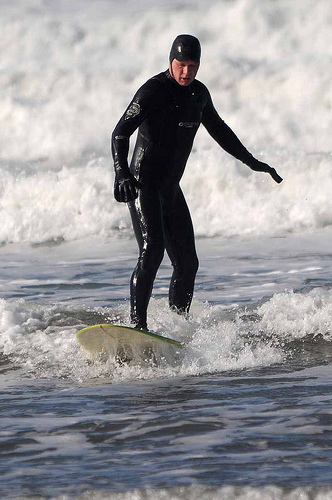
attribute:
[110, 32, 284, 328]
man — surfing, standing, balancing, older, wet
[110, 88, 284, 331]
wet suit — black, whole body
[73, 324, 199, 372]
surf board — green, white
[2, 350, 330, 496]
water — foaming, white, calm, blue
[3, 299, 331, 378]
waves — coming, calm, white, foamy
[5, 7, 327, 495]
ocean — blue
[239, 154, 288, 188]
gloves — black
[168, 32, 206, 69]
hat — black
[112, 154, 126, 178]
label — white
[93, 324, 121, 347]
line — small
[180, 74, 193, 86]
lips — pink